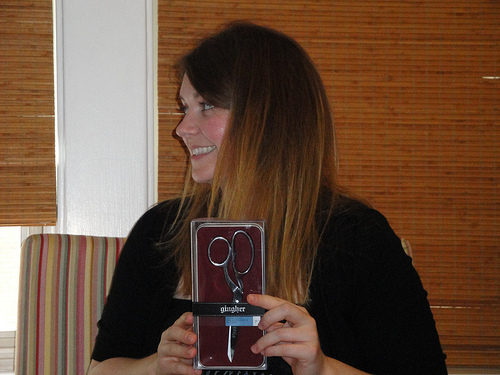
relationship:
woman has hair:
[92, 22, 452, 372] [226, 26, 329, 295]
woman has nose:
[92, 22, 452, 372] [171, 115, 201, 139]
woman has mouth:
[92, 22, 452, 372] [183, 142, 220, 160]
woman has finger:
[92, 22, 452, 372] [245, 290, 288, 309]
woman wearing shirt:
[92, 22, 452, 372] [80, 192, 452, 374]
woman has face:
[92, 22, 452, 372] [169, 73, 233, 184]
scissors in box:
[205, 230, 254, 361] [190, 217, 269, 371]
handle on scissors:
[207, 231, 258, 279] [205, 230, 254, 361]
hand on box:
[248, 290, 327, 374] [190, 217, 269, 371]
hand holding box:
[156, 311, 201, 374] [190, 217, 269, 371]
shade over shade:
[158, 1, 496, 362] [158, 1, 500, 374]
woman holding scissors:
[92, 22, 452, 372] [205, 230, 254, 361]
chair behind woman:
[18, 232, 127, 373] [92, 22, 452, 372]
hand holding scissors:
[248, 290, 327, 374] [205, 230, 254, 361]